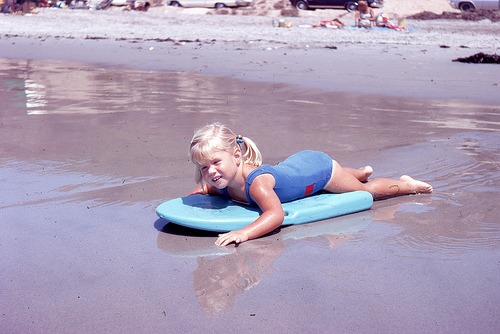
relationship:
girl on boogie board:
[183, 121, 436, 249] [152, 183, 377, 237]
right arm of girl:
[178, 175, 218, 197] [183, 121, 436, 249]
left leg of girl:
[326, 163, 437, 202] [183, 121, 436, 249]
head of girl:
[186, 121, 242, 190] [183, 121, 436, 249]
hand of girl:
[212, 228, 247, 250] [183, 121, 436, 249]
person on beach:
[353, 0, 377, 29] [1, 6, 498, 94]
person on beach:
[374, 10, 405, 32] [1, 6, 498, 94]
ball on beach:
[373, 11, 388, 25] [1, 6, 498, 94]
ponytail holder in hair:
[234, 137, 242, 143] [182, 117, 267, 195]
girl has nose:
[183, 121, 436, 249] [207, 165, 217, 178]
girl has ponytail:
[183, 121, 436, 249] [236, 135, 264, 166]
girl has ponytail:
[183, 121, 436, 249] [192, 162, 207, 196]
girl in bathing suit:
[183, 121, 436, 249] [214, 147, 335, 207]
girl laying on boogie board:
[183, 121, 436, 249] [152, 183, 377, 237]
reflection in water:
[179, 201, 430, 315] [3, 51, 499, 332]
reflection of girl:
[179, 201, 430, 315] [183, 121, 436, 249]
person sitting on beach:
[353, 0, 377, 29] [1, 6, 498, 94]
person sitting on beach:
[374, 10, 405, 32] [1, 6, 498, 94]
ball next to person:
[373, 11, 388, 25] [353, 0, 377, 29]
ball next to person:
[373, 11, 388, 25] [374, 10, 405, 32]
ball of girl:
[373, 11, 388, 25] [183, 121, 436, 249]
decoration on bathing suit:
[301, 182, 315, 198] [214, 147, 335, 207]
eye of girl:
[212, 158, 221, 166] [183, 121, 436, 249]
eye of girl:
[201, 164, 210, 172] [183, 121, 436, 249]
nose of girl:
[207, 165, 217, 178] [183, 121, 436, 249]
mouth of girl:
[209, 173, 222, 185] [183, 121, 436, 249]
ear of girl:
[233, 148, 243, 166] [183, 121, 436, 249]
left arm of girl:
[214, 174, 286, 250] [183, 121, 436, 249]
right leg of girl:
[328, 157, 377, 185] [183, 121, 436, 249]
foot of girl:
[403, 173, 437, 197] [183, 121, 436, 249]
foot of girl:
[356, 162, 376, 183] [183, 121, 436, 249]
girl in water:
[183, 121, 436, 249] [3, 51, 499, 332]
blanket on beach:
[280, 16, 399, 35] [1, 6, 498, 94]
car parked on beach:
[290, 0, 385, 15] [1, 6, 498, 94]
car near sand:
[290, 0, 385, 15] [5, 32, 499, 101]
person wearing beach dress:
[353, 0, 377, 29] [355, 8, 372, 26]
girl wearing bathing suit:
[183, 121, 436, 249] [214, 147, 335, 207]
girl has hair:
[183, 121, 436, 249] [182, 117, 267, 195]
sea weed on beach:
[451, 49, 499, 70] [1, 6, 498, 94]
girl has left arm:
[183, 121, 436, 249] [214, 174, 286, 250]